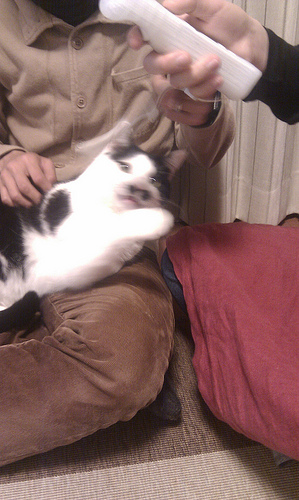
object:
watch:
[209, 86, 221, 114]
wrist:
[188, 83, 222, 132]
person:
[1, 1, 235, 464]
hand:
[1, 146, 58, 208]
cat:
[0, 138, 173, 313]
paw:
[144, 207, 174, 238]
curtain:
[175, 1, 297, 223]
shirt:
[166, 208, 297, 463]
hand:
[126, 0, 252, 100]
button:
[72, 38, 83, 48]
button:
[74, 95, 85, 107]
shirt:
[0, 1, 233, 187]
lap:
[54, 282, 163, 430]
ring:
[168, 91, 182, 112]